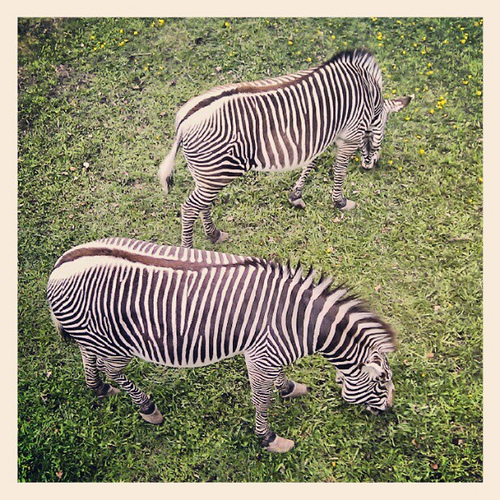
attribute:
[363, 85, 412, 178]
head — White , Black 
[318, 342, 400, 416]
head — Black , White 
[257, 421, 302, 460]
hooves — Large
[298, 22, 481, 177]
flowers — Yellow 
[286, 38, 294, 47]
flower — Yellow 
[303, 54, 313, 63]
flower — Yellow 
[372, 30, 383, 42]
flower — Yellow 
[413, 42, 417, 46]
flower — Yellow 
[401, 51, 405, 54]
flower — Yellow 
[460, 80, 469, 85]
flower — Yellow 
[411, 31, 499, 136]
flowers — Yellow 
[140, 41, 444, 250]
zebra — Grazing 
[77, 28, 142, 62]
flowers — yellow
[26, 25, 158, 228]
grass — Green 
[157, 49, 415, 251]
zebra — White , Black , eating, Grazing 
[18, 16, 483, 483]
grass — Green , healthy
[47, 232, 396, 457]
zebra — Grazing , black, white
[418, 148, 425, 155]
flower — yellow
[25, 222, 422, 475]
zebra — Black , White 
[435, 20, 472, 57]
flowers — Small , Yellow 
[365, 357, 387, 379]
ear — white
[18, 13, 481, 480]
grass field — Green 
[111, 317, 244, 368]
belly — White , Black 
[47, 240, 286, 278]
stripe — black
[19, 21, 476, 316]
grass — Green 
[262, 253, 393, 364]
mane — White , Black 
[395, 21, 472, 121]
flowers — yellow